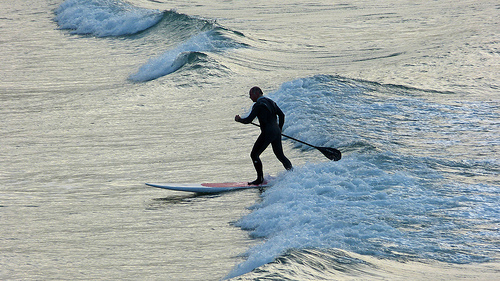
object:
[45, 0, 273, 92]
waves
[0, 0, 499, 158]
ocean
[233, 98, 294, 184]
wet suit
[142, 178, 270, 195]
surfboard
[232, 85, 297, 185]
man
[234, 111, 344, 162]
paddle